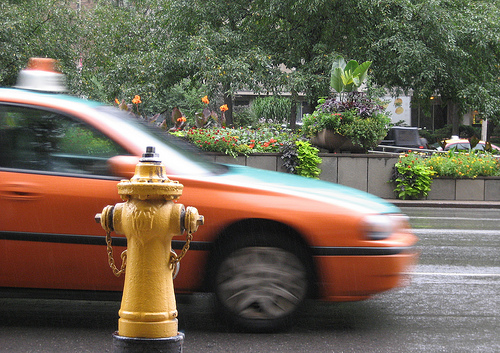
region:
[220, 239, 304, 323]
the front tire on the car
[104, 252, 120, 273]
chain on the fire hydrant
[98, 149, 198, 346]
the fire hydrant is yellow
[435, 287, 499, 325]
the street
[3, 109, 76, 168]
the window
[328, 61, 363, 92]
the green leaves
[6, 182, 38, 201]
handle on the car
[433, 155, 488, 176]
the grass with flowers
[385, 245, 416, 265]
bumper on the car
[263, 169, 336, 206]
hood of the car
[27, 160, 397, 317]
the car is blurry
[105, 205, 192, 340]
the hydrant is yellow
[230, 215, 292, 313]
tire of the car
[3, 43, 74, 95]
top of the taxi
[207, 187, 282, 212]
the taxi is orange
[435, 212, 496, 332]
the road is wet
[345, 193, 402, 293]
front of the car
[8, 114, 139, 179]
window of the car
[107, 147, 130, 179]
mirror of the car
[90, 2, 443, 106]
trees behind the car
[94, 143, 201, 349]
a yellow fire hydrant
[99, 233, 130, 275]
a chain coming off the fire hydrant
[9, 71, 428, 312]
an orange car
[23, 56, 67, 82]
a light on top of the car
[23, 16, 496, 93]
trees behind the street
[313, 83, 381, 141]
flowers in a pot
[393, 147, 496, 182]
flowers next to the road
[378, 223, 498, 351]
the road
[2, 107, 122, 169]
the window of the car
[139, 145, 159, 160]
the tip of a hydrant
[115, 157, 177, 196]
the lid of a hydrant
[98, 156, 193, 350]
a big yellow fire hydrant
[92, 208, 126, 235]
the faucet of a fire hydrant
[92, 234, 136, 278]
the chain of a hydrant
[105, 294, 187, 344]
the base of a hyrdrant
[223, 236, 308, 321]
the wheel of a taxi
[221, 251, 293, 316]
the rim of a wheel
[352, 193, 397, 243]
the headlight of a car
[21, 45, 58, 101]
the sign of a taxi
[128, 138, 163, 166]
the tip of a hydrant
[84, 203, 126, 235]
the faucet of a hydrant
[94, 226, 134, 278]
the chain on a hydrant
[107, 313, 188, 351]
the base of a hydrant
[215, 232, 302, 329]
the tire of a taxi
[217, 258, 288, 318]
the grill of a tire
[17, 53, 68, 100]
the sign on a taxi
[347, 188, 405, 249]
the streetlights on a taxi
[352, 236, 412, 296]
the bumper of a car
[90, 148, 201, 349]
fire hydrant in front of car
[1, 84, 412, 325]
car behind fire hydrant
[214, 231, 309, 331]
wheel belongs to car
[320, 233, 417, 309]
bumper belongs to car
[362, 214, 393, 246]
headlight belongs to car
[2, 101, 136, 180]
window belongs to car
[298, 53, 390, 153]
plant behind car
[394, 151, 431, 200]
plant behind car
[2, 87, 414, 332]
car travels down street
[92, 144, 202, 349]
fire hydrant is painted yellow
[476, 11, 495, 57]
reen leaves on the tree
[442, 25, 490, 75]
reen leaves on the tree